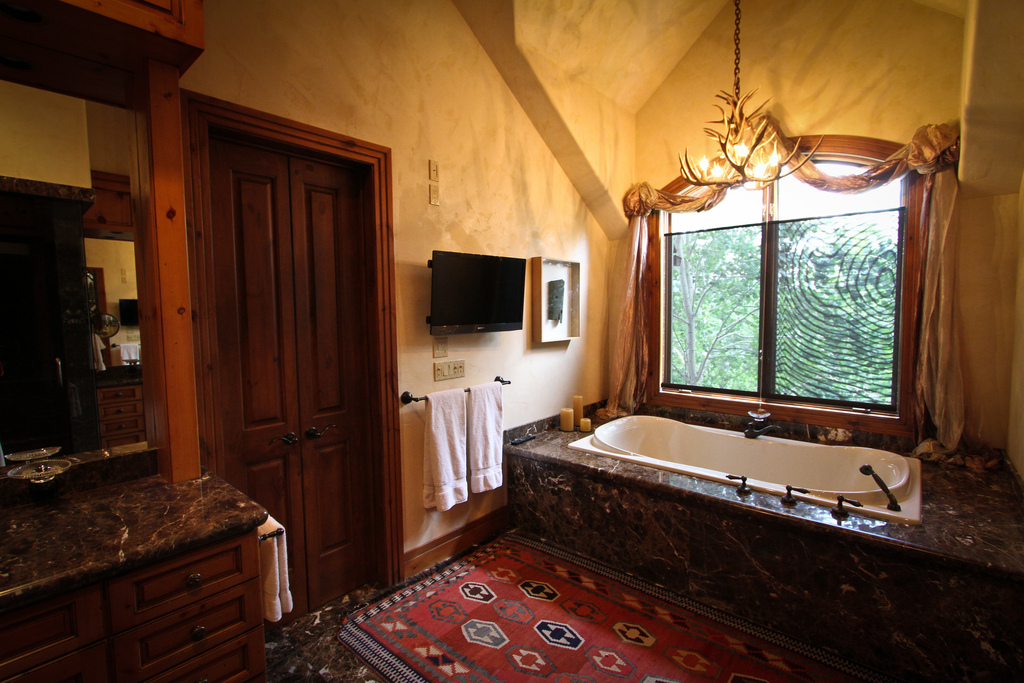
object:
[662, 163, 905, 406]
sunlight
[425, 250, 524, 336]
television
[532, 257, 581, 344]
artwork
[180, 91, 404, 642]
door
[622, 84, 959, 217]
antlers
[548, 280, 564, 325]
item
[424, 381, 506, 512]
towels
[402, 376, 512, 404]
towel rod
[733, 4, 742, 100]
chain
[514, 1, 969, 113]
ceiling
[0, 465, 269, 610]
bathroom top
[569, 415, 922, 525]
bathtub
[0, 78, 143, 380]
mirror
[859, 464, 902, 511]
faucet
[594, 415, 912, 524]
tub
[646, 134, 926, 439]
window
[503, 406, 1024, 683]
counter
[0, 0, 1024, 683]
room